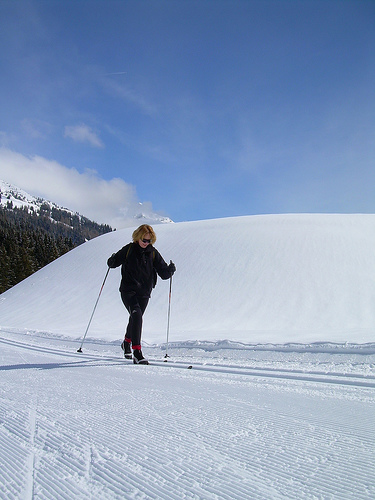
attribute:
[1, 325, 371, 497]
snow — white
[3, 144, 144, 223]
clouds — white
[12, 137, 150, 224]
clouds — white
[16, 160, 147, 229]
clouds — white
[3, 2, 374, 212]
sky — blue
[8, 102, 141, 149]
clouds — white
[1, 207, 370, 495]
snow — white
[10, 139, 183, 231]
clouds — thin, puffy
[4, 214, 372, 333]
mound — smooth snow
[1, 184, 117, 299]
mountain — snow-capped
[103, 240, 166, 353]
outfit — dark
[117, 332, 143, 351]
cuff — red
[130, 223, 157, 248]
hair — middle-parted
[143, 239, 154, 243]
sunglasses — dark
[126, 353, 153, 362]
trim — white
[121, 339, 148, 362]
shoes — black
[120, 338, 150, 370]
shoes — black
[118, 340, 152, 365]
shoes — black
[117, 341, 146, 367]
shoes — black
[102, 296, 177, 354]
pants — black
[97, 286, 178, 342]
pants — black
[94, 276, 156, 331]
pants — black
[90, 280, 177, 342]
pants — black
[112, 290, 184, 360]
pants — black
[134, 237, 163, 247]
shades — dark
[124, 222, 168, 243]
hair — blonde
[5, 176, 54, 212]
snow — white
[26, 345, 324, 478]
snow — lined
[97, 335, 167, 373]
shoes — black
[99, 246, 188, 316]
jacket — black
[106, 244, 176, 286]
jacket — black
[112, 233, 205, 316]
jacket — black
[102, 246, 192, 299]
jacket — black